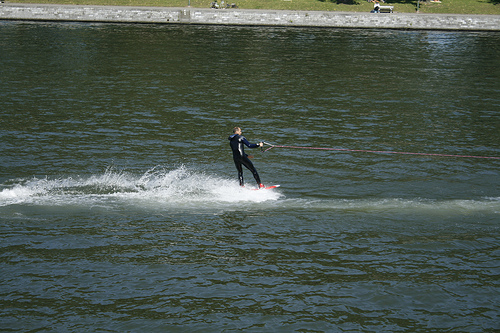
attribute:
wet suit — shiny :
[229, 136, 264, 188]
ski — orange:
[231, 182, 288, 193]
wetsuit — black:
[228, 134, 264, 186]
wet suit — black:
[227, 133, 262, 187]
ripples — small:
[331, 248, 493, 328]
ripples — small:
[47, 247, 57, 254]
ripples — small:
[198, 240, 210, 248]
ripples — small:
[316, 228, 331, 233]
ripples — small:
[351, 155, 366, 163]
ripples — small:
[128, 127, 140, 133]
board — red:
[246, 181, 286, 195]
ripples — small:
[53, 262, 154, 305]